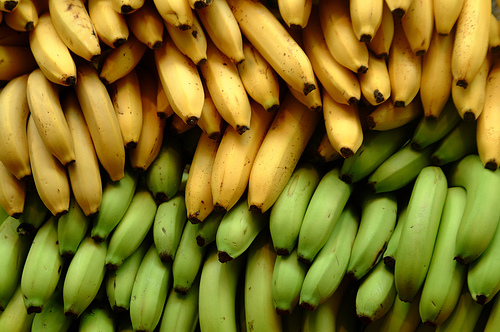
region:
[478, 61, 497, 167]
a ripe banana is hanging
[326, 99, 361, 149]
a ripe banana is hanging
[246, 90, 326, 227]
a ripe banana is hanging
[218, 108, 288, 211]
a ripe banana is hanging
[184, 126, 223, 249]
a ripe banana is hanging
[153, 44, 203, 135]
a ripe banana is hanging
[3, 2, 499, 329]
rows of yellow and green bananas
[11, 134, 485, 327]
rows of green bananas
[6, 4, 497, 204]
rows of yellow bananas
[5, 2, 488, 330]
bunches of yellow and green bananas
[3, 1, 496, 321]
brown ends of bananas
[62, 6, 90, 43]
brown spots on yellow banana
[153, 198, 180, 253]
brown spots on green bananas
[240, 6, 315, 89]
banana with brown spots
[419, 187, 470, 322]
green banana with brown scratch on it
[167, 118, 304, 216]
three yellow bananas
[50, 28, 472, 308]
these are a bunch of bananas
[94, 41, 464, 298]
the bananas are different colors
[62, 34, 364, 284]
the colors are split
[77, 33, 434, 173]
these are yellow bananas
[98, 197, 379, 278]
these are green bananas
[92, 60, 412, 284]
the bananas are in bunches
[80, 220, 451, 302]
the bananas are light green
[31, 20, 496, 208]
the bananas have brown spots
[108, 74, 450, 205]
the ends of the bananas are brown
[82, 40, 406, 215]
the bananas are on display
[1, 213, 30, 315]
green banana in bunch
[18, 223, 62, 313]
green banana in bunch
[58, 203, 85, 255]
green banana in bunch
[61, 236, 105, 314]
green banana in bunch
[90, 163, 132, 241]
green banana in bunch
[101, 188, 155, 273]
green banana in bunch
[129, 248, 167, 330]
green banana in bunch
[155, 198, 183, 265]
green banana in bunch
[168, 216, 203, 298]
green banana in bunch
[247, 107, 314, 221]
yellow banana on bunch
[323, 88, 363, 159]
yellow banana on bunch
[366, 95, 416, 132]
yellow banana on bunch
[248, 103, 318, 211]
yellow banana on bunch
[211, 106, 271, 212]
yellow banana on bunch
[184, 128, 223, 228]
yellow banana on bunch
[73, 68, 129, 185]
yellow banana on bunch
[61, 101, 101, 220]
yellow banana on bunch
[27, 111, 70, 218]
yellow banana on bunch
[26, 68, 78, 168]
yellow banana on bunch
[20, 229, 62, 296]
a banana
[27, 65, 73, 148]
banana is yellow in color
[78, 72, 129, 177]
banana that is yellow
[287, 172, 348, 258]
this is a banana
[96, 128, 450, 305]
Yellow and green fruit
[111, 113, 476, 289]
The fruit is stacked on each other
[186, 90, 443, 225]
Green and yellow fresh fruit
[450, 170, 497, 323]
bunch of green bananas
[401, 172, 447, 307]
bunch of green bananas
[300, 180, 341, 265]
bunch of green bananas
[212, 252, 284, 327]
bunch of green bananas